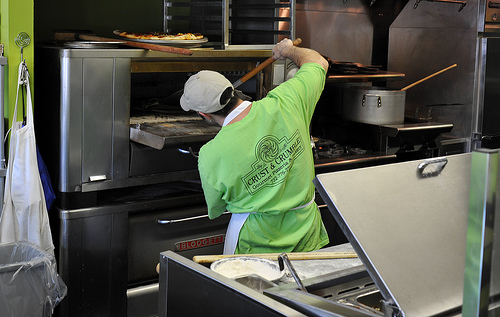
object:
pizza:
[120, 30, 202, 40]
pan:
[110, 26, 210, 47]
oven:
[36, 31, 300, 316]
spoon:
[399, 63, 458, 92]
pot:
[343, 86, 407, 126]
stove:
[309, 118, 469, 251]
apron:
[0, 61, 58, 270]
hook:
[14, 31, 32, 73]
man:
[178, 38, 332, 256]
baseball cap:
[178, 68, 238, 115]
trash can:
[0, 240, 53, 316]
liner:
[0, 239, 68, 317]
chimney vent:
[355, 0, 412, 88]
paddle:
[230, 35, 309, 95]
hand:
[271, 37, 292, 58]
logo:
[239, 129, 306, 197]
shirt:
[194, 62, 329, 257]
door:
[129, 120, 225, 153]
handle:
[188, 145, 199, 158]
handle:
[359, 93, 382, 108]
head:
[178, 69, 246, 127]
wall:
[1, 1, 33, 168]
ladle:
[276, 251, 309, 295]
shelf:
[317, 115, 454, 155]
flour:
[213, 256, 283, 280]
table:
[210, 240, 362, 290]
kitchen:
[1, 1, 500, 316]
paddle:
[50, 28, 196, 58]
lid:
[311, 150, 500, 317]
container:
[324, 283, 384, 316]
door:
[127, 205, 234, 289]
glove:
[270, 37, 294, 60]